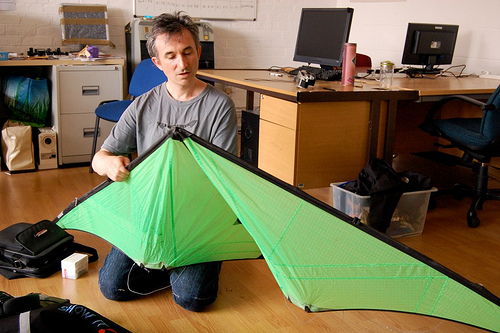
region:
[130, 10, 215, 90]
the face of a man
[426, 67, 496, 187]
a chair at a desk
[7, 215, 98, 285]
a dark back for storage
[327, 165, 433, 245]
a plastic bin filled with stuff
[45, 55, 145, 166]
the front of a filing cabinet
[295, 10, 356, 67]
a computer screen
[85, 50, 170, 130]
a blue chair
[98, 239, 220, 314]
blue jeans worn by a man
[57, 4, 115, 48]
a covered computer screen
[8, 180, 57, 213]
wooden flooring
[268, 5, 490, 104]
Two desktop computers on desk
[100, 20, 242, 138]
guy with grey shirt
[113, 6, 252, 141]
guy with grey hair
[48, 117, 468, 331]
green and black kite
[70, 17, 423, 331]
guy holding kite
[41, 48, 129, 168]
Two storage cabinets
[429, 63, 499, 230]
dark blue computer chair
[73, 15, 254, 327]
guy with blue jeans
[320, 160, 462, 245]
Clear full storage bin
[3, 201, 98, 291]
messenger bag on the floor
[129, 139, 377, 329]
man is holding a kite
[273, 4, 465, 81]
two computer moniters on the desk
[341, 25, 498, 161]
two desk chairs under the desk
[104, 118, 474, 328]
kite is lime green color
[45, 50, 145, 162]
two drawer filing cabinet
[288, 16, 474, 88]
computer moniters are black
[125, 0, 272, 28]
marker board hanging on the wall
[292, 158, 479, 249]
plastic container on the floor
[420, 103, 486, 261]
desk chair has wheels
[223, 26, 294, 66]
wall is white bricks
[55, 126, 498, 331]
a green kite with black edges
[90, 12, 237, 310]
a man in a grey shirt and blue jeans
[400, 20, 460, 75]
a computer monitor on a desk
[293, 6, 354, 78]
a computer monitor on a wooden desk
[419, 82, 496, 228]
a blue chair with wheels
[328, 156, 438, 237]
a plastic tote with a jacket in it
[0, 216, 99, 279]
a black bag on the floor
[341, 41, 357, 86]
a pink container on the desk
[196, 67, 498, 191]
a brown desk with computers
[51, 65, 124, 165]
a filing cabinet with two drawers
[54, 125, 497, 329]
A green kite.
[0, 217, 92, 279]
A small black briefcase bag.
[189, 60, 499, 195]
A brown wooden desk.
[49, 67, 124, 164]
A grey filing cabinet.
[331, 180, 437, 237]
A clear bin full of items.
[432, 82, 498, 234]
A rolling desk chair.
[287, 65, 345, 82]
A black computer keyboard.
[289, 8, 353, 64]
A flat screen black computer monitor.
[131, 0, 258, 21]
The bottom part of a whiteboard.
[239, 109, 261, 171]
A black computer processing unit.